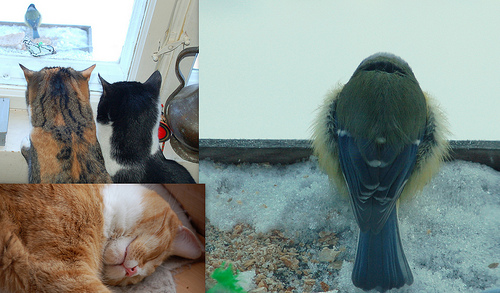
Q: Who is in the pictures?
A: No one.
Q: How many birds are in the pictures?
A: One.